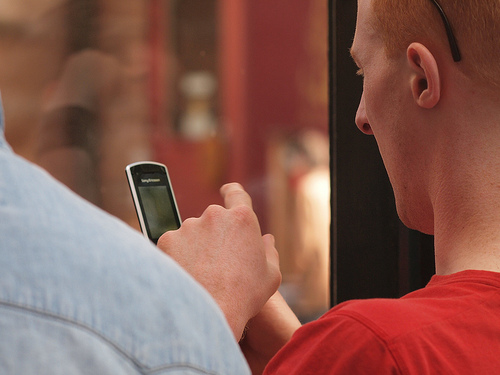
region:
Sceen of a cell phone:
[125, 155, 186, 246]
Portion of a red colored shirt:
[255, 263, 498, 373]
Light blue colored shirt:
[0, 95, 256, 372]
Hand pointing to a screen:
[150, 178, 286, 343]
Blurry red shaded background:
[0, 0, 335, 320]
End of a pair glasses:
[421, 0, 466, 65]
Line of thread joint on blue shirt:
[0, 286, 218, 372]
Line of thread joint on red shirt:
[321, 305, 409, 372]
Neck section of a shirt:
[420, 261, 496, 286]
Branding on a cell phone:
[137, 175, 164, 186]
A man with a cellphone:
[123, 1, 498, 373]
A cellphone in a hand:
[124, 160, 182, 245]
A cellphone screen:
[137, 183, 180, 240]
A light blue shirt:
[0, 102, 253, 374]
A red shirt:
[259, 271, 499, 371]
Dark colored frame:
[329, 0, 434, 311]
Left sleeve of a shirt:
[261, 315, 404, 373]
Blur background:
[1, 0, 328, 327]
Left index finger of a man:
[221, 181, 251, 208]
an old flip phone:
[117, 154, 206, 259]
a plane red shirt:
[258, 265, 498, 373]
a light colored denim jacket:
[9, 128, 252, 373]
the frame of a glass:
[418, 0, 468, 71]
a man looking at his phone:
[122, 3, 498, 371]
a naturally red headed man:
[327, 0, 497, 261]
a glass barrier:
[0, 0, 341, 332]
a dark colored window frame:
[318, 4, 438, 332]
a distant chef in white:
[269, 123, 348, 300]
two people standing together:
[10, 10, 495, 366]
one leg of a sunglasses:
[432, 0, 464, 65]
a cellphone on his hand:
[130, 157, 178, 236]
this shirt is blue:
[0, 156, 237, 373]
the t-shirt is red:
[264, 275, 498, 374]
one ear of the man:
[405, 43, 441, 105]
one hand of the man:
[155, 188, 277, 336]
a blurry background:
[15, 5, 305, 131]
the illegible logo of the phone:
[139, 175, 161, 185]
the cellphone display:
[136, 183, 181, 237]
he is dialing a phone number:
[125, 13, 487, 358]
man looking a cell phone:
[190, 0, 490, 355]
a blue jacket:
[1, 5, 248, 373]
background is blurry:
[1, 0, 336, 301]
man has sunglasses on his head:
[415, 0, 495, 70]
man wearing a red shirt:
[260, 255, 495, 372]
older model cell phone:
[115, 150, 198, 251]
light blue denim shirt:
[0, 137, 250, 372]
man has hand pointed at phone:
[151, 171, 271, 341]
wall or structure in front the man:
[327, 0, 426, 325]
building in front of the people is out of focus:
[0, 2, 342, 305]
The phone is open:
[124, 158, 181, 245]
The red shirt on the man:
[261, 268, 499, 374]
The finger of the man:
[219, 183, 254, 208]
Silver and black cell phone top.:
[123, 159, 183, 246]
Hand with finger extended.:
[155, 181, 280, 328]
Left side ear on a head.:
[406, 42, 441, 109]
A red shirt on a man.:
[260, 269, 498, 374]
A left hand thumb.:
[259, 232, 281, 292]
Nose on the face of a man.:
[355, 84, 378, 136]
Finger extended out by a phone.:
[219, 180, 251, 209]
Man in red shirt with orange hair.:
[155, 1, 498, 374]